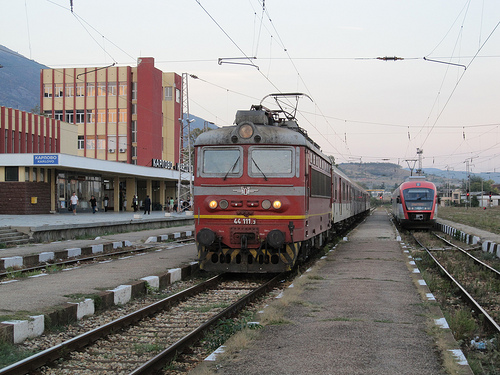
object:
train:
[193, 104, 370, 273]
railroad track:
[410, 229, 500, 332]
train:
[386, 174, 438, 230]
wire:
[422, 57, 467, 71]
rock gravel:
[118, 334, 131, 343]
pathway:
[185, 207, 476, 374]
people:
[65, 192, 79, 216]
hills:
[334, 161, 500, 192]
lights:
[465, 188, 471, 197]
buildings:
[0, 54, 186, 212]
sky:
[0, 0, 500, 173]